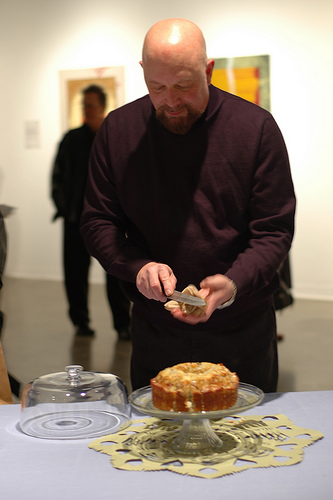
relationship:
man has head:
[76, 16, 294, 389] [129, 16, 217, 131]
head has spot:
[129, 16, 217, 131] [166, 20, 185, 45]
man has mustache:
[76, 16, 294, 389] [154, 102, 190, 112]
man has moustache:
[76, 16, 294, 389] [154, 104, 197, 127]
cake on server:
[150, 359, 238, 412] [129, 381, 265, 450]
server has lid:
[129, 381, 265, 450] [15, 362, 134, 440]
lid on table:
[15, 362, 134, 440] [2, 390, 333, 499]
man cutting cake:
[76, 16, 294, 389] [150, 359, 238, 412]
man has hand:
[76, 16, 294, 389] [136, 260, 181, 302]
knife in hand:
[166, 287, 206, 308] [136, 260, 181, 302]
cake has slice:
[150, 359, 238, 412] [166, 283, 206, 313]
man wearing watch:
[76, 16, 294, 389] [216, 275, 237, 309]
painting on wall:
[56, 62, 123, 134] [2, 1, 332, 299]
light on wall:
[32, 20, 144, 143] [2, 1, 332, 299]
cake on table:
[150, 359, 238, 412] [2, 390, 333, 499]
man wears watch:
[76, 16, 294, 389] [216, 275, 237, 309]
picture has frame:
[213, 71, 257, 103] [208, 54, 272, 110]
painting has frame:
[68, 75, 119, 128] [56, 62, 123, 134]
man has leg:
[49, 86, 107, 338] [61, 221, 99, 338]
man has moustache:
[76, 16, 294, 389] [154, 104, 193, 114]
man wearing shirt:
[76, 16, 294, 389] [78, 89, 297, 309]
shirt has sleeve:
[78, 89, 297, 309] [227, 120, 297, 297]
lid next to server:
[15, 362, 134, 440] [129, 381, 265, 450]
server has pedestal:
[129, 381, 265, 450] [168, 421, 239, 458]